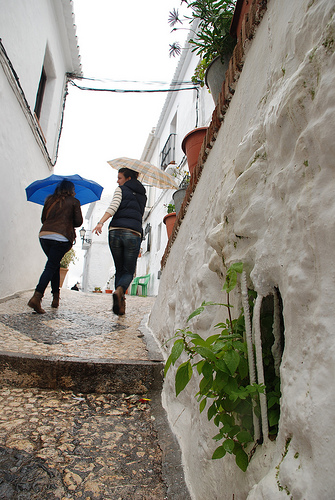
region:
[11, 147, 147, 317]
women with umbrellas in hands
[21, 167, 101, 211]
blue umbrella on woman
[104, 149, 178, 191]
light colored umbrella on woman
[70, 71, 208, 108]
wires connecting between buildings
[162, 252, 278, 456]
plant growth in rock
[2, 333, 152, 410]
stone step on a walkway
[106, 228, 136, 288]
pants on a woman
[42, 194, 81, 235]
jacket on a woman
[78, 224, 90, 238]
light on side of building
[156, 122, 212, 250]
pots with plants in them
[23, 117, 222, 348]
woman walking outside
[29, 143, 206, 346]
woman walking in the rain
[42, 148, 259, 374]
two woman walking outside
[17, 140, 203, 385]
two woman walking in the rain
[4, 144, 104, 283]
a woman holding a blue umbrella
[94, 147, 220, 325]
a woman holding a plaid umbrella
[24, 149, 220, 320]
woman holding umbrellas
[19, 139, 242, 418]
two women holding umbrellas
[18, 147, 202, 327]
a woman wearing a jacket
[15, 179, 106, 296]
a woman wearing a brown jacket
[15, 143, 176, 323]
two girls carrying umbrellas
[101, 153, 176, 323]
a girl with a plaid umbrella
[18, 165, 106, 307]
a girl with a blue umbrella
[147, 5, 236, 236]
plants on a brick wall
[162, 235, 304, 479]
a plant growing through a hole in the wall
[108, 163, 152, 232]
a girl wearing a vest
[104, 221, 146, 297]
a girl wearing jeans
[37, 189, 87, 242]
a girl wearing a brown jacket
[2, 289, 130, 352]
a diamond pattern on a step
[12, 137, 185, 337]
two ladies with umbrellas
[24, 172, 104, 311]
a woman beneath a blue umbrella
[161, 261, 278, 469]
ivy on a white wall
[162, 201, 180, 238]
a green plant in a terracotta pot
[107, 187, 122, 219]
a white sleeve with blue lines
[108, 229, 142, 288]
woman wearing blue jeans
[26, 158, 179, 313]
two women walking under the rain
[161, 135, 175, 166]
a black fence balcony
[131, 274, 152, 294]
a green plastic chair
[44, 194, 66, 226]
a leather strap on woman's back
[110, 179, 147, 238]
woman wearing a blue vest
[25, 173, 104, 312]
woman with a blue umbrella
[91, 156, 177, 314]
woman with a white and orange umbrella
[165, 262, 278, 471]
plant coming out of a wall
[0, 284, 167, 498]
road made of stone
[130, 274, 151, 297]
empty green chair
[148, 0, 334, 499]
white stone wall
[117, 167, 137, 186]
head of a woman looking to the left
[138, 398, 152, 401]
yellow and orange leaf on the ground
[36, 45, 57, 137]
window of a white building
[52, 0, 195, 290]
white skies